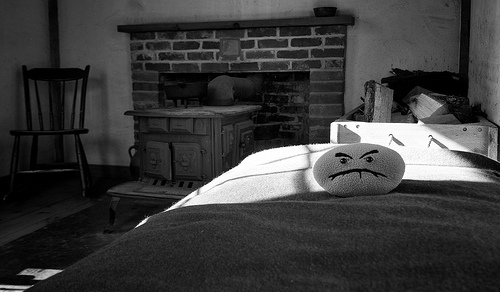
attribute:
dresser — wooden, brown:
[105, 105, 262, 231]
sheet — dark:
[25, 177, 498, 289]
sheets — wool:
[208, 124, 445, 290]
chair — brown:
[3, 55, 105, 209]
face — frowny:
[303, 144, 426, 193]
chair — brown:
[4, 62, 98, 194]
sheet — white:
[198, 144, 337, 188]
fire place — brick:
[91, 6, 378, 211]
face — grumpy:
[311, 138, 397, 187]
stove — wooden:
[97, 75, 273, 226]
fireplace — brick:
[93, 2, 389, 219]